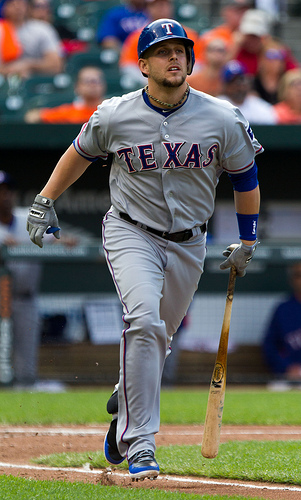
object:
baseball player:
[61, 12, 269, 449]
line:
[1, 453, 100, 485]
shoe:
[126, 451, 162, 478]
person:
[24, 66, 104, 123]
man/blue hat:
[220, 59, 248, 102]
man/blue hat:
[92, 16, 264, 366]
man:
[27, 66, 103, 120]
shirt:
[39, 103, 95, 121]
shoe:
[103, 417, 128, 465]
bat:
[195, 240, 259, 464]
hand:
[216, 230, 262, 280]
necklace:
[143, 84, 189, 106]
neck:
[146, 77, 187, 108]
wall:
[18, 256, 295, 374]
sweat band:
[234, 209, 260, 241]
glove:
[25, 194, 60, 247]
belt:
[117, 208, 208, 245]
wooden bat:
[202, 252, 235, 458]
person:
[217, 57, 278, 128]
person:
[271, 70, 299, 124]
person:
[25, 16, 266, 481]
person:
[0, 0, 64, 79]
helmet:
[142, 20, 174, 35]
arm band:
[231, 207, 263, 244]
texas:
[112, 131, 218, 180]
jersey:
[79, 87, 263, 237]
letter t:
[156, 20, 175, 33]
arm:
[219, 97, 261, 270]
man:
[28, 19, 262, 477]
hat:
[136, 18, 195, 66]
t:
[160, 20, 172, 35]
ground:
[176, 429, 249, 491]